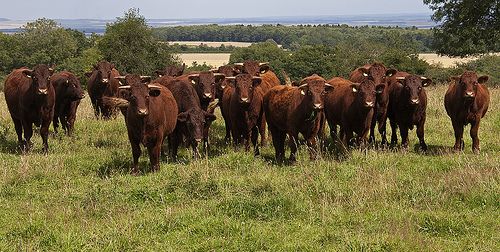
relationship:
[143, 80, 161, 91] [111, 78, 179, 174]
horn on cow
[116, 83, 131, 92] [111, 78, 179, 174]
horn on cow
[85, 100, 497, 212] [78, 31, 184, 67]
trees with branches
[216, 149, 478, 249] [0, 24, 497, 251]
shadow in field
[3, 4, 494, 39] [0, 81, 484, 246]
sun on field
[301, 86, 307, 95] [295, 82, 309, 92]
tag on ear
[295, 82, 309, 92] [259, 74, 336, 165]
ear of cow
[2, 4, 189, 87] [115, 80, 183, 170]
trees behind cow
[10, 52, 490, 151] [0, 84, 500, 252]
herd grazing on grass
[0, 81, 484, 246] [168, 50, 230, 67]
field of dried grass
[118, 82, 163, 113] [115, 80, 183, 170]
head of cow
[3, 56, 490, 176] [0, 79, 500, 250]
cows in field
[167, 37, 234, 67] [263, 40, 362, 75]
dirt between trees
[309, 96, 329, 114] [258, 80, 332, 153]
mouth of cow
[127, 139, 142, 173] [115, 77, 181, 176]
leg of cow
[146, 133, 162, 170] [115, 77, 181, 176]
leg of cow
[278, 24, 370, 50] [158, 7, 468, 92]
trees in forest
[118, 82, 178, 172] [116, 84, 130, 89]
cow has horn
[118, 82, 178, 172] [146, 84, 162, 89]
cow has horn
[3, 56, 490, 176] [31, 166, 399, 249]
cows eat grass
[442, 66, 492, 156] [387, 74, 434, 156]
cow away from cattle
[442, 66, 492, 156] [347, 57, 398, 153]
cow away from cow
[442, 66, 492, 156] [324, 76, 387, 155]
cow away from cattle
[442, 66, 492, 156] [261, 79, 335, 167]
cow away from cattle